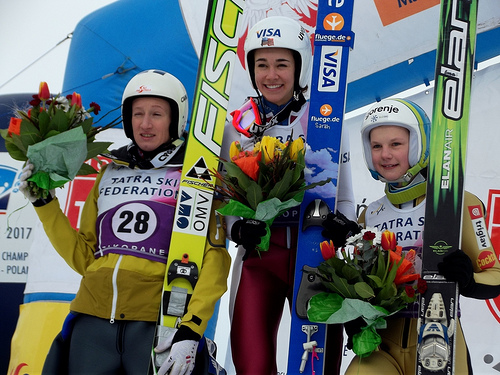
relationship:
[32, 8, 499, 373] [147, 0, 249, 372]
people are holding skis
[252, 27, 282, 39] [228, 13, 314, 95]
logo on helmet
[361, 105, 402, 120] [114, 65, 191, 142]
logo on helmet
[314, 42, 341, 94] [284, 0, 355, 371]
logo on ski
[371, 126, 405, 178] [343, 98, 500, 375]
face of girl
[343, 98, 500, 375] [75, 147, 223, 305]
girl wearing a jacket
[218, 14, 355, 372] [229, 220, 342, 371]
lady wearing red pants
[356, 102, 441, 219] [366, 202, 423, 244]
girl wearing shirt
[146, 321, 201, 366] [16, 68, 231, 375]
glove on people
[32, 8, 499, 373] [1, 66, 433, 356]
people holding flowers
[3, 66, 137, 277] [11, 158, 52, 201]
flowers in woman's hand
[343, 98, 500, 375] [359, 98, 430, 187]
girl wearing helmet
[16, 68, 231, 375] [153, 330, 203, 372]
people wearing glove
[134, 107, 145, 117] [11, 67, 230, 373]
eye of woman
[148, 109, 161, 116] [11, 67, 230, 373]
eye of woman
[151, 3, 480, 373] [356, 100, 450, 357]
skis next to women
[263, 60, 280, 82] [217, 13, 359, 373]
nose of woman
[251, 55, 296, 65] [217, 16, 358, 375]
eyebrows of lady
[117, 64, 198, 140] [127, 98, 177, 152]
helmet on head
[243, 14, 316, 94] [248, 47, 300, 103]
helmet on head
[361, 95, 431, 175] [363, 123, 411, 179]
helmet on head